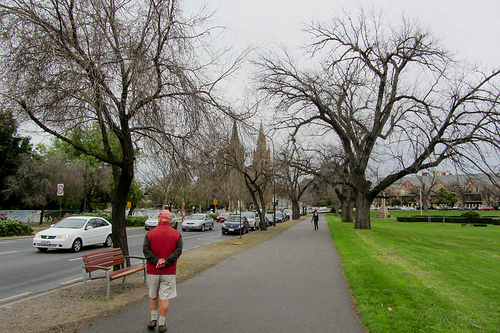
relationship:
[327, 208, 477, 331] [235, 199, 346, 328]
field next to sidewalk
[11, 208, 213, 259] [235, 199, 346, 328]
road next to sidewalk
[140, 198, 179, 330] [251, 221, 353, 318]
person on sidewalk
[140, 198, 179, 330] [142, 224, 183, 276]
person has on red jacket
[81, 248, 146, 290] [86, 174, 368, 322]
red bench on sidewalk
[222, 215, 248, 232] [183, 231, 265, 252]
car on street edge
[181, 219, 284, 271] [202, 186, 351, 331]
grass next to sidewalk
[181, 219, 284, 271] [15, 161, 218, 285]
grass next to road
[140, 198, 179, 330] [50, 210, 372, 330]
person on sidewalk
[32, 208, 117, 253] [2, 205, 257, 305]
car on street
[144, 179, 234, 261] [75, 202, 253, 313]
car on street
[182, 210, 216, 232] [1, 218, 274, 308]
car on street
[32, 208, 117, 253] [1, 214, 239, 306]
car on street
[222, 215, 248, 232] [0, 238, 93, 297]
car on street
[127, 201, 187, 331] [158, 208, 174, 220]
man wearing cap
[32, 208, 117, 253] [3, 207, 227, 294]
car in street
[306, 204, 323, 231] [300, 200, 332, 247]
person on sidewalk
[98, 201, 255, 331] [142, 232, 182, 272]
man wearing vest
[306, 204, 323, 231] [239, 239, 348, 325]
person on sidewalk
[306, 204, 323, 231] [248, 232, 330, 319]
person on sidewalk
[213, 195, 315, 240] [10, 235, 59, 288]
car on street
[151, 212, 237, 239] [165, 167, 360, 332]
car on street